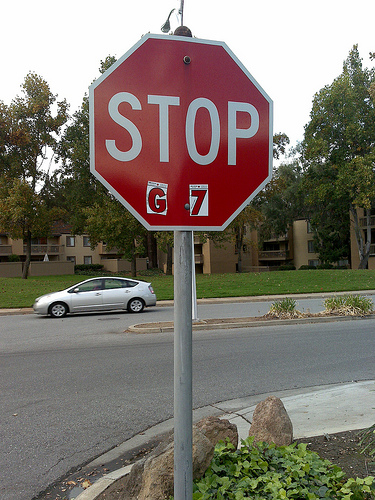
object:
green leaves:
[313, 135, 342, 155]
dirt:
[296, 426, 373, 496]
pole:
[172, 229, 193, 497]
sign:
[88, 31, 273, 496]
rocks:
[115, 414, 240, 497]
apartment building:
[0, 225, 170, 273]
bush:
[184, 440, 375, 497]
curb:
[128, 406, 237, 463]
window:
[65, 235, 75, 247]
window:
[82, 235, 93, 248]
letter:
[105, 91, 144, 164]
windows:
[103, 278, 127, 289]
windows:
[66, 236, 76, 248]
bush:
[269, 299, 299, 319]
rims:
[51, 305, 65, 317]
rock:
[247, 393, 292, 449]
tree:
[295, 44, 375, 272]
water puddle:
[36, 466, 96, 497]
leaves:
[197, 483, 208, 493]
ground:
[290, 422, 375, 492]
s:
[104, 90, 142, 163]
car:
[31, 273, 156, 318]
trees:
[263, 161, 318, 268]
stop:
[105, 86, 261, 167]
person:
[89, 277, 105, 291]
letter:
[184, 96, 221, 166]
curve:
[64, 380, 356, 497]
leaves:
[369, 182, 370, 183]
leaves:
[370, 49, 372, 57]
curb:
[0, 289, 369, 316]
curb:
[33, 434, 156, 500]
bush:
[319, 282, 372, 314]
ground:
[202, 308, 363, 327]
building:
[0, 199, 372, 282]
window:
[65, 255, 76, 265]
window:
[83, 255, 92, 264]